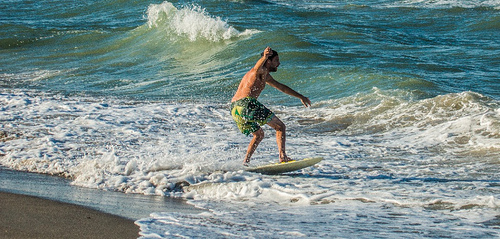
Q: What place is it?
A: It is an ocean.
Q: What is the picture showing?
A: It is showing an ocean.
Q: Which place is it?
A: It is an ocean.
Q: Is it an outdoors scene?
A: Yes, it is outdoors.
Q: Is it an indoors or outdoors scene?
A: It is outdoors.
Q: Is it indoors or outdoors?
A: It is outdoors.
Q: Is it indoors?
A: No, it is outdoors.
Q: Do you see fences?
A: No, there are no fences.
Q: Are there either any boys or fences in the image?
A: No, there are no fences or boys.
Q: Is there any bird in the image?
A: No, there are no birds.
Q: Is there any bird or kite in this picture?
A: No, there are no birds or kites.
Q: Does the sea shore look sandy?
A: Yes, the sea shore is sandy.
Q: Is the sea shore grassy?
A: No, the sea shore is sandy.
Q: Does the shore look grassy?
A: No, the shore is sandy.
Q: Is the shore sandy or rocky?
A: The shore is sandy.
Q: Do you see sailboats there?
A: No, there are no sailboats.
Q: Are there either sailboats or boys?
A: No, there are no sailboats or boys.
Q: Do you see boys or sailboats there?
A: No, there are no sailboats or boys.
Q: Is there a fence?
A: No, there are no fences.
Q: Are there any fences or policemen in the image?
A: No, there are no fences or policemen.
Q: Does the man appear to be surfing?
A: Yes, the man is surfing.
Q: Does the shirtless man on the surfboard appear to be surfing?
A: Yes, the man is surfing.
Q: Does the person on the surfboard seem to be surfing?
A: Yes, the man is surfing.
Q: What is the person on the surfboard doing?
A: The man is surfing.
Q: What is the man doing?
A: The man is surfing.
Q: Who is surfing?
A: The man is surfing.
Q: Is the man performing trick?
A: No, the man is surfing.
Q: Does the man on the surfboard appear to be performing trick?
A: No, the man is surfing.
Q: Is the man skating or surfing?
A: The man is surfing.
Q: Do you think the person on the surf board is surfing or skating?
A: The man is surfing.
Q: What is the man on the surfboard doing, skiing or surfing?
A: The man is surfing.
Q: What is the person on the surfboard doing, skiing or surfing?
A: The man is surfing.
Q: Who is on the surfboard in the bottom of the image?
A: The man is on the surf board.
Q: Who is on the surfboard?
A: The man is on the surf board.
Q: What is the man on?
A: The man is on the surfboard.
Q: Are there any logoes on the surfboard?
A: No, there is a man on the surfboard.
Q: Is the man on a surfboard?
A: Yes, the man is on a surfboard.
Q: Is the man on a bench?
A: No, the man is on a surfboard.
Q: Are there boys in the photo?
A: No, there are no boys.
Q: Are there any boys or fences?
A: No, there are no boys or fences.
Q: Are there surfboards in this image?
A: Yes, there is a surfboard.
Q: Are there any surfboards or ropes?
A: Yes, there is a surfboard.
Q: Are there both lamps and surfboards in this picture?
A: No, there is a surfboard but no lamps.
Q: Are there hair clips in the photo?
A: No, there are no hair clips.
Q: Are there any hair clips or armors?
A: No, there are no hair clips or armors.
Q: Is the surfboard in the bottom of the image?
A: Yes, the surfboard is in the bottom of the image.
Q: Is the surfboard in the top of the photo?
A: No, the surfboard is in the bottom of the image.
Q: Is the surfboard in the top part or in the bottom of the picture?
A: The surfboard is in the bottom of the image.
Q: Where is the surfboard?
A: The surfboard is in the ocean.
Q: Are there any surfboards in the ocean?
A: Yes, there is a surfboard in the ocean.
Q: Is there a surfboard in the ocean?
A: Yes, there is a surfboard in the ocean.